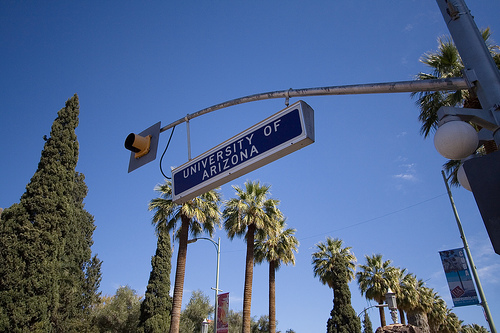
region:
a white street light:
[435, 105, 473, 157]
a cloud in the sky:
[385, 151, 422, 192]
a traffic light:
[120, 124, 157, 168]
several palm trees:
[238, 192, 289, 332]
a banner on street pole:
[430, 244, 487, 307]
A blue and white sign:
[175, 112, 306, 199]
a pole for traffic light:
[183, 75, 398, 112]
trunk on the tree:
[269, 269, 277, 331]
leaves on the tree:
[0, 172, 84, 324]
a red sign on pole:
[215, 251, 230, 331]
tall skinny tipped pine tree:
[0, 82, 121, 318]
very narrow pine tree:
[131, 183, 183, 330]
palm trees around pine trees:
[157, 155, 370, 332]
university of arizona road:
[76, 49, 489, 328]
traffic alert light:
[101, 113, 179, 174]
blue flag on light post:
[419, 212, 489, 319]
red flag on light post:
[204, 282, 243, 332]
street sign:
[148, 81, 321, 285]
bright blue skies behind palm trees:
[42, 78, 443, 331]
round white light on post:
[395, 84, 495, 164]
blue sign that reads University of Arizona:
[135, 97, 320, 201]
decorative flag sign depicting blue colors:
[431, 235, 481, 309]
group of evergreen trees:
[6, 72, 103, 332]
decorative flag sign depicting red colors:
[215, 287, 230, 327]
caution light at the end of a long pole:
[115, 115, 165, 175]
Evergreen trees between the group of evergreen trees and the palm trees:
[135, 199, 183, 329]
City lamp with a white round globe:
[430, 91, 495, 156]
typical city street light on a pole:
[185, 227, 221, 329]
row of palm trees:
[230, 185, 495, 330]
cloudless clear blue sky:
[17, 19, 428, 130]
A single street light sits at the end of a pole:
[104, 111, 167, 174]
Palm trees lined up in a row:
[153, 179, 455, 326]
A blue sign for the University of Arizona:
[153, 84, 350, 217]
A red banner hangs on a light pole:
[206, 284, 234, 328]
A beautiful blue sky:
[54, 8, 253, 89]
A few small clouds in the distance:
[385, 137, 419, 195]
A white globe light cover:
[421, 105, 491, 169]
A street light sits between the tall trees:
[179, 231, 238, 289]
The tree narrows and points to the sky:
[2, 84, 114, 308]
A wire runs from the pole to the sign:
[146, 120, 191, 185]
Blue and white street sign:
[168, 101, 313, 193]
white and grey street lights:
[422, 107, 494, 189]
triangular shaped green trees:
[4, 86, 171, 331]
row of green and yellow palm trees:
[156, 159, 478, 324]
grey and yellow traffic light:
[117, 127, 165, 164]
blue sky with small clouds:
[0, 1, 448, 79]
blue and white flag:
[432, 247, 482, 307]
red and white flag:
[214, 287, 231, 331]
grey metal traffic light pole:
[157, 65, 484, 125]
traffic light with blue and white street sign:
[100, 65, 497, 195]